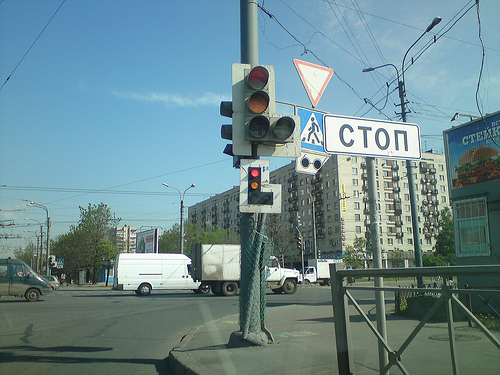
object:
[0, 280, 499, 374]
ground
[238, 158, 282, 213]
stop light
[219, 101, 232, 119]
stop light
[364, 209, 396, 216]
balcony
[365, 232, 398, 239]
balcony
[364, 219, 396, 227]
balcony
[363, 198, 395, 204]
balcony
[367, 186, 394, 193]
balcony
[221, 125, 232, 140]
traffic light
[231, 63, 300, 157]
stop light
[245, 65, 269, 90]
traffic light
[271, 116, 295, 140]
traffic light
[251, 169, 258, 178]
traffic light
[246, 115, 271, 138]
traffic light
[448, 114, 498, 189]
sign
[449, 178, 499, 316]
building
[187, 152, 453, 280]
building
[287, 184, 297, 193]
terrace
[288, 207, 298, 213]
terrace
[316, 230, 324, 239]
terrace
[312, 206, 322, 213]
terrace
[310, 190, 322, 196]
terrace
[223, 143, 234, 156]
traffic light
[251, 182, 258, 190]
traffic light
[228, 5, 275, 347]
pole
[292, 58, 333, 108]
sign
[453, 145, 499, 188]
hamburger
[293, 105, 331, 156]
sign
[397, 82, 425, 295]
post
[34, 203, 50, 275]
lamp posts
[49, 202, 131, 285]
trees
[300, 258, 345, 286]
truck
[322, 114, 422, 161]
sign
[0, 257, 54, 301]
mini van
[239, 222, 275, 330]
fencing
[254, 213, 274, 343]
wire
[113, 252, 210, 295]
mini van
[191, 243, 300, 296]
truck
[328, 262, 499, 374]
gate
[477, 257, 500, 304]
wall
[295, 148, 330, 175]
sign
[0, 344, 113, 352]
shadows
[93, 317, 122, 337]
stains